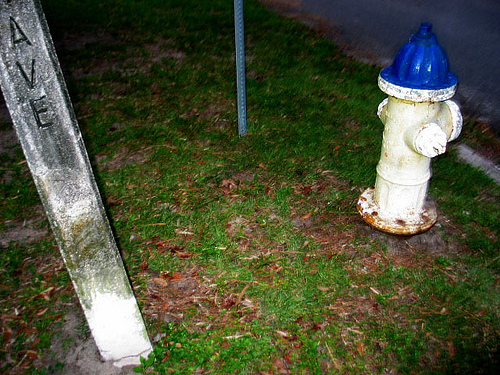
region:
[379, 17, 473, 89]
blue top of fire hydrant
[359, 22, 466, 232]
fire hydrant on side of road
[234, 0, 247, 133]
silver metal sign pole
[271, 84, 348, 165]
ground covered in grass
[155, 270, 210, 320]
leaves laying on ground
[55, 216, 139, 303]
moss growing on stone post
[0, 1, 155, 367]
stone street post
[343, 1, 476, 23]
pavement on road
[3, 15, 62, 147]
engraving on side of stone post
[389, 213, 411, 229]
bolt on bottom of fire hydrant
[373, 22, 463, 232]
White fire hydrant with blue top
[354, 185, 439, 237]
Rusty base of white fire hydrant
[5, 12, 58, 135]
Letters carved into concrete post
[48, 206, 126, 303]
Green moss growing on concrete post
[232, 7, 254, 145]
Thin metal pole in grass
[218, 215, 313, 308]
Green grass covered with debris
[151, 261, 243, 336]
Twigs and leaves scattered on ground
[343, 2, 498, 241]
White and blue hydrant next to road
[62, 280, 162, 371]
White paint on bottom of concrete post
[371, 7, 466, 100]
Bright blue top of hydrant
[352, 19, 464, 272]
The fire hydrant has a blue top.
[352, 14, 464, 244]
The fire hydrant has a white bottom.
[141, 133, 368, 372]
The grass is sparse.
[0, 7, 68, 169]
The pole has lettering on it.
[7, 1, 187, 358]
The pole is wood.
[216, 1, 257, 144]
the pole is metal.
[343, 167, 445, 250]
The fire hydrant has rust.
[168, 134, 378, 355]
The sticks are on the ground.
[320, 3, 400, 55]
The road is concrete.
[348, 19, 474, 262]
The fire hydrant is in the ground.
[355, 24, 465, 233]
a rusty blue and white fire hydrant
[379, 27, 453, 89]
a blue painted top of a fire hydrant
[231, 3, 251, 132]
a metal long pole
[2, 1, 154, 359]
a crooked concrete stone pillar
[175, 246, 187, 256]
a brownish red wet leaf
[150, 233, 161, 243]
a brownish red wet leaf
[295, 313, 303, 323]
a brownish red wet leaf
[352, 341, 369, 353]
a brownish red wet leaf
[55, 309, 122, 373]
a patch of dirt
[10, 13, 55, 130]
the word AVE in pillar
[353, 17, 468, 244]
blue tip on white fire hydrant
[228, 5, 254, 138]
green iron pole with holes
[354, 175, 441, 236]
rusty brown spots at bottom of fire hydrant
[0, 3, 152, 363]
letters indented into gray post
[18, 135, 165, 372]
white smudges on gray post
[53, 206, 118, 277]
green moss growing on gray cement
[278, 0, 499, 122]
gray concrete next to grass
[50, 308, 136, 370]
patch of gray dirt next to concrete post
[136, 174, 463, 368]
brown patches on green grass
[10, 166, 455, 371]
traces of autumn leaves on the grass